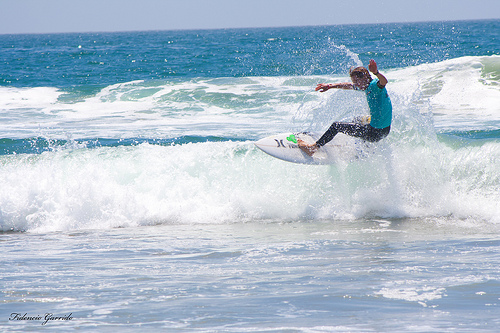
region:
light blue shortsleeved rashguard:
[356, 74, 398, 138]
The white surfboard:
[250, 128, 344, 165]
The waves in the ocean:
[2, 53, 499, 237]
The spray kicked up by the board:
[299, 33, 435, 140]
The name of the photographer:
[6, 304, 76, 324]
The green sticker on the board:
[285, 130, 302, 145]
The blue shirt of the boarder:
[351, 76, 398, 133]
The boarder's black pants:
[320, 114, 390, 155]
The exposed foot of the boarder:
[295, 136, 323, 160]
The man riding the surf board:
[295, 53, 395, 155]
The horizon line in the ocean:
[0, 7, 498, 42]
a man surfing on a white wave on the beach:
[257, 60, 392, 165]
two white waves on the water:
[1, 53, 498, 237]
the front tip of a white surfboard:
[255, 130, 296, 164]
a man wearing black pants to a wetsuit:
[295, 58, 393, 155]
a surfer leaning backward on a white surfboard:
[252, 59, 392, 167]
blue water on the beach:
[4, 35, 256, 73]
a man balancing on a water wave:
[255, 57, 392, 164]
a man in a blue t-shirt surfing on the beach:
[2, 18, 498, 326]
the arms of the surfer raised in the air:
[314, 59, 389, 95]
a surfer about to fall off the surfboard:
[255, 59, 392, 165]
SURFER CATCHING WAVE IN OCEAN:
[278, 44, 391, 178]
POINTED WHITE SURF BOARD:
[246, 111, 398, 167]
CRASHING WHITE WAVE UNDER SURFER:
[2, 141, 483, 232]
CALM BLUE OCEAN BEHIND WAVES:
[19, 32, 495, 89]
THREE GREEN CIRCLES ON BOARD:
[285, 126, 301, 151]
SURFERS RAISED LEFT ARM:
[366, 55, 399, 85]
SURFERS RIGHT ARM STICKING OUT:
[300, 71, 370, 101]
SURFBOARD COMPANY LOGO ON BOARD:
[275, 131, 290, 146]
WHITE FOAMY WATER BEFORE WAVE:
[49, 238, 402, 329]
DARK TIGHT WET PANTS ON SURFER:
[307, 107, 392, 151]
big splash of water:
[94, 154, 225, 326]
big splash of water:
[76, 132, 206, 274]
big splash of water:
[114, 148, 194, 255]